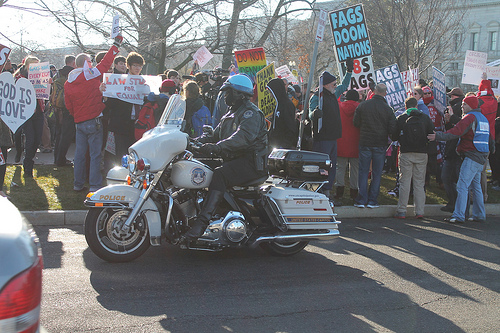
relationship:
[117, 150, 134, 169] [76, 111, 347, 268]
light on front of motorcycle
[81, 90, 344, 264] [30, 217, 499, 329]
motorcycle on street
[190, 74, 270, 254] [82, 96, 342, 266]
cop on bike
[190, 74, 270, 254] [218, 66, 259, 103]
cop wearing helmet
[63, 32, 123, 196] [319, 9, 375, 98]
man carrying signs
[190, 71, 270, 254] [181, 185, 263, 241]
cop wearing boots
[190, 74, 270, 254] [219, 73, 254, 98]
cop wearing helmet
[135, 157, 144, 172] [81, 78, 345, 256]
red light on motorcycle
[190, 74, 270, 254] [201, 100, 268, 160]
cop wearing coat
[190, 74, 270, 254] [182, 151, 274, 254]
cop wearing pants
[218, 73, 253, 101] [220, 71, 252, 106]
helmet on head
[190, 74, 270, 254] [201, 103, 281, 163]
cop wearing coat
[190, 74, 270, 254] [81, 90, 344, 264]
cop sitting on motorcycle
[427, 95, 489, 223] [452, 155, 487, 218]
person wearing pants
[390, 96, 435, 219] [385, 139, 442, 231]
man wearing pants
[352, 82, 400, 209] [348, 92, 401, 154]
man wearing jacket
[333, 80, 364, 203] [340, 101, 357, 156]
person wearing red coat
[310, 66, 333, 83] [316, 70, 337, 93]
hat on head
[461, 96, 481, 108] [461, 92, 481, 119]
hat on head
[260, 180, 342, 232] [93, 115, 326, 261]
container on bike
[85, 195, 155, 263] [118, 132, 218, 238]
tire on bike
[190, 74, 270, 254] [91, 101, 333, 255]
cop on bike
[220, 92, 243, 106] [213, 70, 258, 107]
black mask on face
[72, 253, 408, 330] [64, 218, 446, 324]
shadow on ground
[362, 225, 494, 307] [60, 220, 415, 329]
cast on street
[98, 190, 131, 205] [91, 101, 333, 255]
wording on bike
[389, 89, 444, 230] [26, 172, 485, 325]
man on street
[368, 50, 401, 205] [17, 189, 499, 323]
man standing in street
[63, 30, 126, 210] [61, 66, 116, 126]
man has jacket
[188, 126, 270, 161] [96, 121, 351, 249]
bars on motorcycle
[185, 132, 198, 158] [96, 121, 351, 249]
handle bars on motorcycle